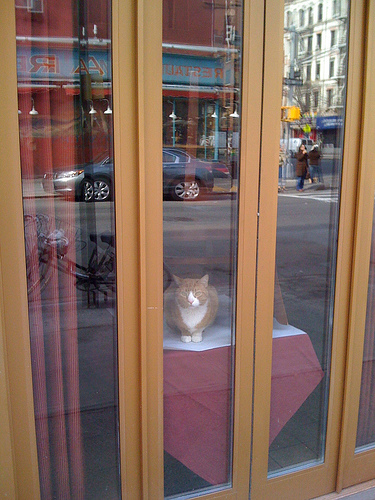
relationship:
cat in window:
[159, 268, 220, 344] [0, 0, 374, 499]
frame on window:
[1, 0, 42, 499] [0, 0, 374, 499]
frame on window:
[110, 2, 166, 497] [0, 0, 374, 499]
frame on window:
[230, 1, 284, 499] [0, 0, 374, 499]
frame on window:
[323, 0, 374, 491] [0, 0, 374, 499]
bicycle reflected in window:
[24, 214, 174, 311] [0, 0, 374, 499]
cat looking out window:
[159, 268, 220, 344] [0, 0, 374, 499]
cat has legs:
[159, 268, 220, 344] [180, 327, 203, 342]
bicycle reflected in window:
[25, 203, 178, 311] [0, 0, 374, 499]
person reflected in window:
[294, 140, 310, 190] [0, 0, 374, 499]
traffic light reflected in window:
[282, 101, 302, 122] [0, 0, 374, 499]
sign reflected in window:
[281, 106, 301, 123] [0, 0, 374, 499]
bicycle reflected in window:
[24, 214, 174, 311] [0, 0, 146, 498]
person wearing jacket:
[294, 142, 309, 192] [293, 148, 307, 174]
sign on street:
[282, 103, 302, 121] [25, 158, 339, 308]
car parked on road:
[41, 146, 232, 201] [61, 183, 322, 255]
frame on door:
[0, 0, 374, 499] [18, 12, 358, 486]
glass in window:
[268, 0, 350, 478] [0, 0, 374, 499]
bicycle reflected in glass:
[24, 214, 174, 311] [16, 52, 120, 493]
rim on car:
[173, 179, 200, 201] [41, 144, 232, 201]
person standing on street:
[294, 142, 309, 192] [25, 158, 339, 308]